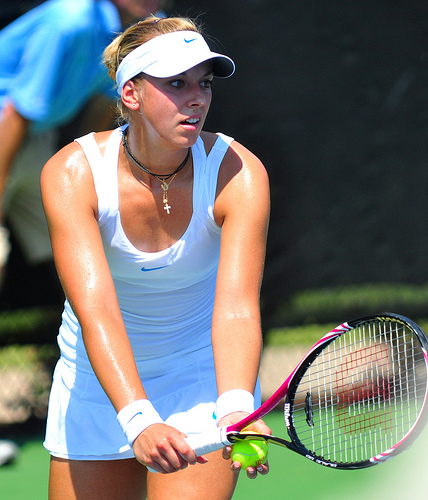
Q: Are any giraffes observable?
A: No, there are no giraffes.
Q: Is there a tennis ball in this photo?
A: Yes, there is a tennis ball.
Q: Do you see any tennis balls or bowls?
A: Yes, there is a tennis ball.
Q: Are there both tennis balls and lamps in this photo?
A: No, there is a tennis ball but no lamps.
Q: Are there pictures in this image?
A: No, there are no pictures.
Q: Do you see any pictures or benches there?
A: No, there are no pictures or benches.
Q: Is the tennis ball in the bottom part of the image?
A: Yes, the tennis ball is in the bottom of the image.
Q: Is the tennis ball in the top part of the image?
A: No, the tennis ball is in the bottom of the image.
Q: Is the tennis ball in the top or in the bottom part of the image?
A: The tennis ball is in the bottom of the image.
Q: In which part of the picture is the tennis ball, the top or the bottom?
A: The tennis ball is in the bottom of the image.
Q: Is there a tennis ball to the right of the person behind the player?
A: Yes, there is a tennis ball to the right of the person.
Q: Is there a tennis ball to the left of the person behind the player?
A: No, the tennis ball is to the right of the person.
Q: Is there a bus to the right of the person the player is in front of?
A: No, there is a tennis ball to the right of the person.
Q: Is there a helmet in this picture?
A: No, there are no helmets.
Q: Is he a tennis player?
A: Yes, this is a tennis player.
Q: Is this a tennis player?
A: Yes, this is a tennis player.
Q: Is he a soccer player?
A: No, this is a tennis player.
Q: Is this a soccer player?
A: No, this is a tennis player.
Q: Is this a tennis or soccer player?
A: This is a tennis player.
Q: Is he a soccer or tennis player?
A: This is a tennis player.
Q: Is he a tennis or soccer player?
A: This is a tennis player.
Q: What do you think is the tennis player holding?
A: The player is holding the tennis ball.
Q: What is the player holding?
A: The player is holding the tennis ball.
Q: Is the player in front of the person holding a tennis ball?
A: Yes, the player is holding a tennis ball.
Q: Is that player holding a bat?
A: No, the player is holding a tennis ball.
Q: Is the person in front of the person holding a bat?
A: No, the player is holding a tennis ball.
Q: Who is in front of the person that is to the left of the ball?
A: The player is in front of the person.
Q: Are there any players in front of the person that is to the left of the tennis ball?
A: Yes, there is a player in front of the person.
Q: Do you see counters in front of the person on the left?
A: No, there is a player in front of the person.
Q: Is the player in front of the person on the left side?
A: Yes, the player is in front of the person.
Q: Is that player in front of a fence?
A: No, the player is in front of the person.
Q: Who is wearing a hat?
A: The player is wearing a hat.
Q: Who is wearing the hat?
A: The player is wearing a hat.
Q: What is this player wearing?
A: The player is wearing a hat.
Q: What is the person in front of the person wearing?
A: The player is wearing a hat.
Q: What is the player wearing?
A: The player is wearing a hat.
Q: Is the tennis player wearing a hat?
A: Yes, the player is wearing a hat.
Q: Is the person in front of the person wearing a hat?
A: Yes, the player is wearing a hat.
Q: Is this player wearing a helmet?
A: No, the player is wearing a hat.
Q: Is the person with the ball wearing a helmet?
A: No, the player is wearing a hat.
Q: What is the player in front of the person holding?
A: The player is holding the tennis ball.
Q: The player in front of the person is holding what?
A: The player is holding the tennis ball.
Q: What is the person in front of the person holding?
A: The player is holding the tennis ball.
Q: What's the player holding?
A: The player is holding the tennis ball.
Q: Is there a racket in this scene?
A: Yes, there is a racket.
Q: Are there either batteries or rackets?
A: Yes, there is a racket.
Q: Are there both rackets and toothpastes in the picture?
A: No, there is a racket but no toothpastes.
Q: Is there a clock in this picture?
A: No, there are no clocks.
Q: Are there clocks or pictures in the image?
A: No, there are no clocks or pictures.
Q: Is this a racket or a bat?
A: This is a racket.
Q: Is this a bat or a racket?
A: This is a racket.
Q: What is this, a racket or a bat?
A: This is a racket.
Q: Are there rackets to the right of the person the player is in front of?
A: Yes, there is a racket to the right of the person.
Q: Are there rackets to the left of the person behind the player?
A: No, the racket is to the right of the person.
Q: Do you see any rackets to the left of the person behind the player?
A: No, the racket is to the right of the person.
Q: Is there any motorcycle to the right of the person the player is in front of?
A: No, there is a racket to the right of the person.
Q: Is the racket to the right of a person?
A: Yes, the racket is to the right of a person.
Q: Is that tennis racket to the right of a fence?
A: No, the tennis racket is to the right of a person.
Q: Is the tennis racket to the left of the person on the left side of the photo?
A: No, the tennis racket is to the right of the person.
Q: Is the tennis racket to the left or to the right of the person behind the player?
A: The tennis racket is to the right of the person.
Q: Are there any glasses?
A: No, there are no glasses.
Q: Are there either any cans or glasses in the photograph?
A: No, there are no glasses or cans.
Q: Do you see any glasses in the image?
A: No, there are no glasses.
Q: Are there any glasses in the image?
A: No, there are no glasses.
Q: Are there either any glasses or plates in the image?
A: No, there are no glasses or plates.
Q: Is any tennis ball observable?
A: Yes, there is a tennis ball.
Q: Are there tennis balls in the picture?
A: Yes, there is a tennis ball.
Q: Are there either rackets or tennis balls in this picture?
A: Yes, there is a tennis ball.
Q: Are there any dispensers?
A: No, there are no dispensers.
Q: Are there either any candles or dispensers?
A: No, there are no dispensers or candles.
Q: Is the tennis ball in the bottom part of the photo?
A: Yes, the tennis ball is in the bottom of the image.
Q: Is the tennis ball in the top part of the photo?
A: No, the tennis ball is in the bottom of the image.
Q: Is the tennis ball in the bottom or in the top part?
A: The tennis ball is in the bottom of the image.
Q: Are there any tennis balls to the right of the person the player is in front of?
A: Yes, there is a tennis ball to the right of the person.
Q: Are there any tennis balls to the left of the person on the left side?
A: No, the tennis ball is to the right of the person.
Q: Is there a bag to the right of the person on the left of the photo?
A: No, there is a tennis ball to the right of the person.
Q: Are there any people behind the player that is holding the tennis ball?
A: Yes, there is a person behind the player.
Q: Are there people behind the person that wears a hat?
A: Yes, there is a person behind the player.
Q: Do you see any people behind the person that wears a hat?
A: Yes, there is a person behind the player.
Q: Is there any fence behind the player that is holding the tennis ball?
A: No, there is a person behind the player.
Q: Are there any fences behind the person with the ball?
A: No, there is a person behind the player.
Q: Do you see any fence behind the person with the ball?
A: No, there is a person behind the player.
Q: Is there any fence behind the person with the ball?
A: No, there is a person behind the player.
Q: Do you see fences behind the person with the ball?
A: No, there is a person behind the player.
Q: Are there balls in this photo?
A: Yes, there is a ball.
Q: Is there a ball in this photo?
A: Yes, there is a ball.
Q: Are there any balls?
A: Yes, there is a ball.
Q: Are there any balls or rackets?
A: Yes, there is a ball.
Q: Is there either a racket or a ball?
A: Yes, there is a ball.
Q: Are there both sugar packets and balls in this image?
A: No, there is a ball but no sugar packets.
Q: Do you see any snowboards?
A: No, there are no snowboards.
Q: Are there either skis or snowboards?
A: No, there are no snowboards or skis.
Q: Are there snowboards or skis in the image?
A: No, there are no snowboards or skis.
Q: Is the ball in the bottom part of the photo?
A: Yes, the ball is in the bottom of the image.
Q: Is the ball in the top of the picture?
A: No, the ball is in the bottom of the image.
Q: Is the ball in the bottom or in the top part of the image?
A: The ball is in the bottom of the image.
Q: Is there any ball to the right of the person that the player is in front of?
A: Yes, there is a ball to the right of the person.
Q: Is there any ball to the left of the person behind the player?
A: No, the ball is to the right of the person.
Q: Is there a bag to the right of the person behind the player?
A: No, there is a ball to the right of the person.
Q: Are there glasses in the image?
A: No, there are no glasses.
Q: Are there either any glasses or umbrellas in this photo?
A: No, there are no glasses or umbrellas.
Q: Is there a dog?
A: No, there are no dogs.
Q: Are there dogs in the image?
A: No, there are no dogs.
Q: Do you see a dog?
A: No, there are no dogs.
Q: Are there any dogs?
A: No, there are no dogs.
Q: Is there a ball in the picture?
A: Yes, there is a ball.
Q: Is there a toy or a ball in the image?
A: Yes, there is a ball.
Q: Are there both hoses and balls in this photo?
A: No, there is a ball but no hoses.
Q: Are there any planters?
A: No, there are no planters.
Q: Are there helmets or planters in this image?
A: No, there are no planters or helmets.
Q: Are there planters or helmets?
A: No, there are no planters or helmets.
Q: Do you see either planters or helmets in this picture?
A: No, there are no planters or helmets.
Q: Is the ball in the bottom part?
A: Yes, the ball is in the bottom of the image.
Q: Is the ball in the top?
A: No, the ball is in the bottom of the image.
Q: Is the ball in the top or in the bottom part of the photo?
A: The ball is in the bottom of the image.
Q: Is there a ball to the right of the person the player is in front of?
A: Yes, there is a ball to the right of the person.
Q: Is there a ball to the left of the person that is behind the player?
A: No, the ball is to the right of the person.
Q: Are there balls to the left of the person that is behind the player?
A: No, the ball is to the right of the person.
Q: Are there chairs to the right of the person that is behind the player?
A: No, there is a ball to the right of the person.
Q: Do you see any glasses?
A: No, there are no glasses.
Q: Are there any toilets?
A: No, there are no toilets.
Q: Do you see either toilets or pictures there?
A: No, there are no toilets or pictures.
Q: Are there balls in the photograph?
A: Yes, there is a ball.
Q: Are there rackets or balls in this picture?
A: Yes, there is a ball.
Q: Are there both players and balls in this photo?
A: Yes, there are both a ball and a player.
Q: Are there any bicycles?
A: No, there are no bicycles.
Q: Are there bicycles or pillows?
A: No, there are no bicycles or pillows.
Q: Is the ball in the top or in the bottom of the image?
A: The ball is in the bottom of the image.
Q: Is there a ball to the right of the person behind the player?
A: Yes, there is a ball to the right of the person.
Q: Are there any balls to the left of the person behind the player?
A: No, the ball is to the right of the person.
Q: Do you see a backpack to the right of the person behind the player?
A: No, there is a ball to the right of the person.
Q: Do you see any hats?
A: Yes, there is a hat.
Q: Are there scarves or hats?
A: Yes, there is a hat.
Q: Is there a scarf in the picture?
A: No, there are no scarves.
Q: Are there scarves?
A: No, there are no scarves.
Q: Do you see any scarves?
A: No, there are no scarves.